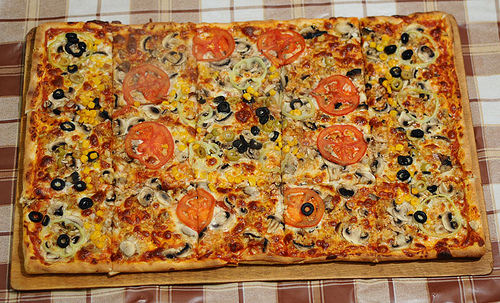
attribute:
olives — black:
[206, 85, 277, 155]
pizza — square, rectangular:
[13, 10, 483, 271]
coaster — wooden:
[8, 21, 482, 290]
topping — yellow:
[217, 168, 243, 183]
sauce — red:
[439, 55, 453, 102]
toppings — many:
[38, 30, 437, 239]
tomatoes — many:
[121, 25, 368, 231]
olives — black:
[379, 30, 415, 80]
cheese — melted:
[292, 156, 315, 178]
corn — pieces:
[238, 80, 258, 107]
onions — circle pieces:
[44, 217, 85, 257]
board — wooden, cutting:
[5, 10, 484, 296]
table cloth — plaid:
[4, 7, 484, 299]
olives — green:
[391, 151, 413, 184]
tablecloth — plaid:
[3, 11, 484, 297]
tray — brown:
[5, 10, 485, 290]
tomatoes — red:
[178, 182, 324, 227]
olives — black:
[27, 192, 102, 247]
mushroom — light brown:
[443, 210, 464, 240]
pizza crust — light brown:
[12, 233, 498, 272]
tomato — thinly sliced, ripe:
[116, 115, 178, 172]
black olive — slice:
[64, 30, 93, 54]